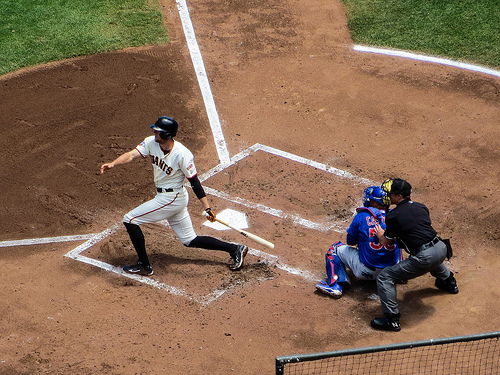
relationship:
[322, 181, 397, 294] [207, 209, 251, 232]
catcher behind home plate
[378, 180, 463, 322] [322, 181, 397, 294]
umpire behind catcher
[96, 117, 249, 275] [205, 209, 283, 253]
player holding bat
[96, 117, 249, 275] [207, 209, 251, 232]
player at home plate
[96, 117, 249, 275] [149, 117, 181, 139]
player wearing a helmet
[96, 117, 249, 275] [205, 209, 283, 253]
player swinging a bat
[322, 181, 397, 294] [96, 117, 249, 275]
catcher behind player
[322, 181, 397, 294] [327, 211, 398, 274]
catcher wears uniform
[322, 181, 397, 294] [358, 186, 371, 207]
catcher wears a mask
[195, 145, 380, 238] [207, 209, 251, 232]
batters box around home plate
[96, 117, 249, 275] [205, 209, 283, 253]
player about to drop bat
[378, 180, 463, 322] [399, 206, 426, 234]
umpire wears black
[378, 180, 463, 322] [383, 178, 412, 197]
umpire wears hat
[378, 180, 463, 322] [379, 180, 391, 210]
umpire wearing a mask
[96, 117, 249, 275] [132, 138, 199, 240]
player wearing a uniform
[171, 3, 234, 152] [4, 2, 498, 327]
line on field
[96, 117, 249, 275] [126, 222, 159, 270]
player wears socks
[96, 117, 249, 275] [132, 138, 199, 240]
player in uniform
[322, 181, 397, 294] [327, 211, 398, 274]
catcher wears a uniform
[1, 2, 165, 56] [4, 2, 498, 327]
grass on field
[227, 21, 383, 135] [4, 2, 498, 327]
dirt on field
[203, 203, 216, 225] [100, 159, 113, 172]
glove on hand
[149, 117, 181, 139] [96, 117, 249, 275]
helmet on player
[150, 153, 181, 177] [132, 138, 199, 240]
name on uniform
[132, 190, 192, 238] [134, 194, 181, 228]
pants have stripe